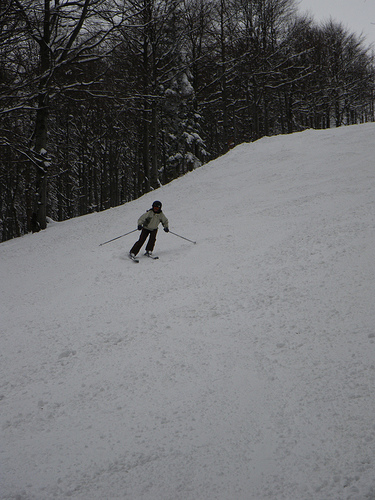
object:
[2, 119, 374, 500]
snow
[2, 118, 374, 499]
slope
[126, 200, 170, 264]
skier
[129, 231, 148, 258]
leg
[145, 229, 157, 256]
leg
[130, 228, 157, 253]
trousers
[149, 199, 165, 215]
head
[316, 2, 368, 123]
trees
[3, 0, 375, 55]
sky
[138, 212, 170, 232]
jacket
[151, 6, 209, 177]
tree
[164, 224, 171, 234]
gloves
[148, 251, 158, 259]
feet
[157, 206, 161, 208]
goggles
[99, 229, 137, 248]
poles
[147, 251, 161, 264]
skies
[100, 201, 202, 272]
skiing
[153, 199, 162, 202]
helmet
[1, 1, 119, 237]
tree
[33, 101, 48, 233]
trunk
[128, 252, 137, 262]
edge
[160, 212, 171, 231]
arm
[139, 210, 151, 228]
side